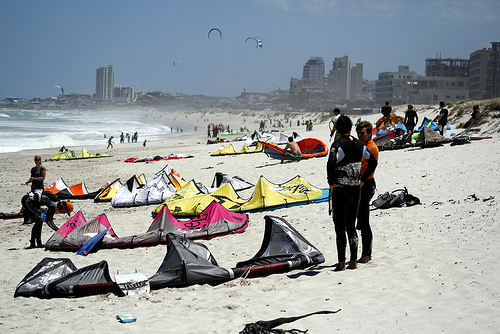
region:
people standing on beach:
[305, 123, 385, 276]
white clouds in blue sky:
[23, 16, 57, 41]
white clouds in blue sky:
[66, 30, 116, 53]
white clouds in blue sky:
[232, 0, 285, 41]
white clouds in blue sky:
[220, 27, 246, 50]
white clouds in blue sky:
[331, 10, 373, 36]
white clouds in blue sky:
[380, 16, 419, 52]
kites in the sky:
[167, 23, 264, 66]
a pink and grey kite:
[45, 205, 250, 241]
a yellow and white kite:
[150, 178, 320, 209]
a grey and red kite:
[10, 215, 325, 290]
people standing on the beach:
[325, 115, 377, 267]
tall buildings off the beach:
[290, 42, 496, 107]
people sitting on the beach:
[180, 107, 496, 145]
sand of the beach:
[375, 210, 496, 330]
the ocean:
[0, 107, 170, 142]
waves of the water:
[7, 112, 84, 143]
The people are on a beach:
[18, 8, 469, 330]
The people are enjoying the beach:
[11, 23, 481, 318]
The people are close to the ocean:
[16, 36, 487, 331]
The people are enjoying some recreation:
[11, 42, 496, 323]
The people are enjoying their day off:
[25, 35, 467, 330]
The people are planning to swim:
[10, 25, 492, 325]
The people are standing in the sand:
[10, 30, 491, 325]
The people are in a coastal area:
[10, 37, 491, 328]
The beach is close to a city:
[16, 40, 487, 321]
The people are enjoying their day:
[17, 30, 469, 320]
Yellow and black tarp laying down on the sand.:
[192, 175, 236, 219]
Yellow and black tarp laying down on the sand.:
[102, 306, 149, 327]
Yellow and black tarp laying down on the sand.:
[17, 242, 112, 294]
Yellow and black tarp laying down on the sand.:
[383, 188, 427, 209]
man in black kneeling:
[21, 188, 73, 246]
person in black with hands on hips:
[326, 115, 377, 269]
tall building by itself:
[95, 64, 115, 101]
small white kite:
[256, 35, 263, 47]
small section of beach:
[1, 108, 191, 153]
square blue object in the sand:
[116, 313, 135, 323]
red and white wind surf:
[125, 152, 193, 159]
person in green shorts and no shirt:
[279, 137, 301, 162]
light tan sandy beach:
[2, 107, 499, 332]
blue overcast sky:
[1, 0, 497, 96]